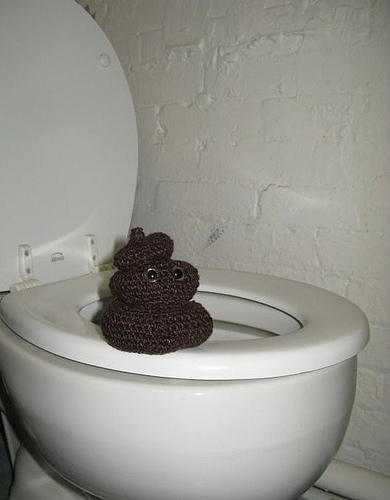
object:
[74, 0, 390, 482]
brick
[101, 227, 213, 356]
black frog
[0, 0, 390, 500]
toilet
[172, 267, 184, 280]
eye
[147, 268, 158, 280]
eye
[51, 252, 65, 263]
logo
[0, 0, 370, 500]
toilet bowl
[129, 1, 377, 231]
cracks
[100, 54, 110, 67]
bolt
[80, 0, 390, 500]
toilet wall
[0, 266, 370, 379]
seat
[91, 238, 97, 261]
bolt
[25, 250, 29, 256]
bolt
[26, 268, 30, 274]
bolt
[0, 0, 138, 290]
cover